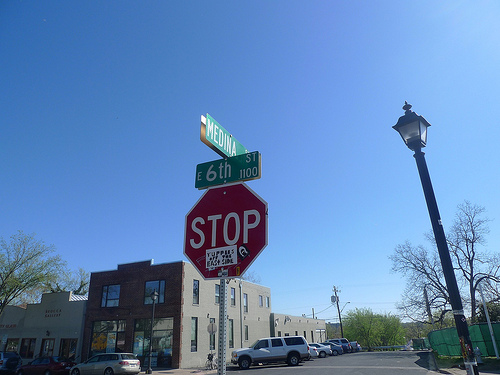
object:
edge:
[171, 260, 190, 370]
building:
[78, 259, 279, 372]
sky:
[4, 0, 105, 103]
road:
[174, 350, 451, 374]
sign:
[180, 179, 274, 283]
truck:
[230, 335, 309, 370]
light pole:
[390, 98, 487, 374]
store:
[3, 288, 87, 371]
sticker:
[201, 243, 238, 270]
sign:
[190, 148, 263, 191]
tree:
[384, 202, 498, 336]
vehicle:
[308, 343, 321, 362]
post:
[329, 283, 349, 339]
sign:
[196, 110, 244, 158]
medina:
[207, 118, 237, 153]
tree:
[0, 227, 63, 339]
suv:
[0, 349, 24, 374]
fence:
[419, 324, 499, 359]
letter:
[217, 160, 227, 181]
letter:
[245, 153, 253, 166]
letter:
[249, 149, 259, 163]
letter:
[196, 168, 204, 183]